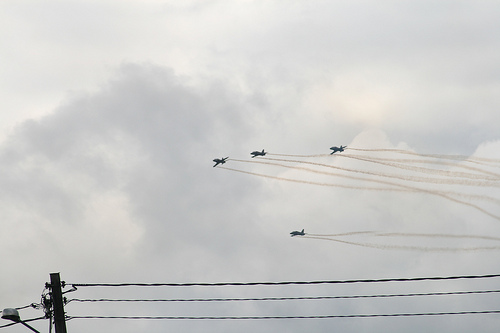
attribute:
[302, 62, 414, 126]
white cloud — bright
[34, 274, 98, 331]
pole — black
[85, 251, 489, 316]
power lines — Overhead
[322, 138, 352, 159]
plane —  in air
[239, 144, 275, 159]
plane —  in air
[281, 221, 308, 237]
plane —  in air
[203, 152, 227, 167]
plane —  in air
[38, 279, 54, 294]
knob — Pea knob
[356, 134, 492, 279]
smoke —  in air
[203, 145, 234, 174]
plane — leading plane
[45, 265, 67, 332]
pole — power pole, Electrical power pole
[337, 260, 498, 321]
lines — black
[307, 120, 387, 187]
plane — fourth plane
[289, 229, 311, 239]
plane — lowest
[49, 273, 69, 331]
pole — power